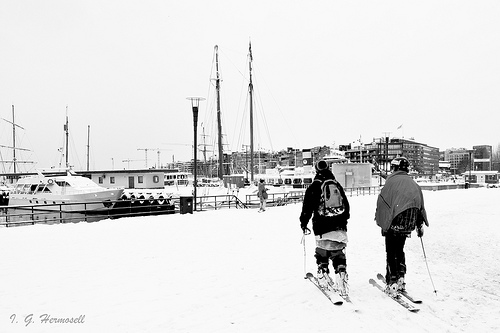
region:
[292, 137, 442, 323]
Two people skiing toward the harbor.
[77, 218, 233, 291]
White snow on the ground.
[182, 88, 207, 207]
Tall light at the harbor.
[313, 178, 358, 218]
Wearing a back pack while skiing.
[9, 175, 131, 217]
Boat in the very cold water.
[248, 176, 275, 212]
Woman walking on the pier.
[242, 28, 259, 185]
Tall masts on a sail boat.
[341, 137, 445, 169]
Apartment building in the distance.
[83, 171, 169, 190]
Boat house on the pier.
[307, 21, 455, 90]
Cold grey sky during winter.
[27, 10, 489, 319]
Black and white photo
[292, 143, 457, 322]
two people on skis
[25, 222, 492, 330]
The ground is white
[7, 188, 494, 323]
Snow on the ground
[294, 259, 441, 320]
Ski's on the people's feet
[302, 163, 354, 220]
Backpack on the back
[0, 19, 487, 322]
Photo taken during the day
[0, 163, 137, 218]
Boat parked at a dock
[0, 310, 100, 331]
T.G. Hormosell photograph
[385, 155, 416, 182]
Helmet on the person's head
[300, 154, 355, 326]
person on skis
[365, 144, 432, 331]
person wearing hat and jacket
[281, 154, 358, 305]
person using ski poles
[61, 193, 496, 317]
a lot of snow on the ground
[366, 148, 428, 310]
person wearing black pants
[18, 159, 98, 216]
white boat in the water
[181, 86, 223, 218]
light pole by the pier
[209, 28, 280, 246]
ships masts poking out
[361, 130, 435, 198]
buildings by the pier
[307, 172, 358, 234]
person wearing a backpack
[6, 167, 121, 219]
a boat in the water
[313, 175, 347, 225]
the person has a backpack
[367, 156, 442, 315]
the person on the right is holding a ski pole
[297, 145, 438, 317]
both people are wearing hats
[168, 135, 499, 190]
buildings in front of the people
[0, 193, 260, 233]
a railing in front of the boat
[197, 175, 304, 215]
a person is standing near the railing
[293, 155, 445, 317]
the people are wearing coats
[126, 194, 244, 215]
a trash can by the railing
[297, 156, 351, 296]
A person on some skis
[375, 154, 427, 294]
A person on some skis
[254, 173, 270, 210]
A person walking in the snow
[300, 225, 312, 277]
A ski pole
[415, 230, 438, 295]
A ski pole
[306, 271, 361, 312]
A pair of skis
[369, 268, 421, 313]
A pair of skis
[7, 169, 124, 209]
a boat on the water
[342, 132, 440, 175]
A large building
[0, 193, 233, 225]
A guard rail